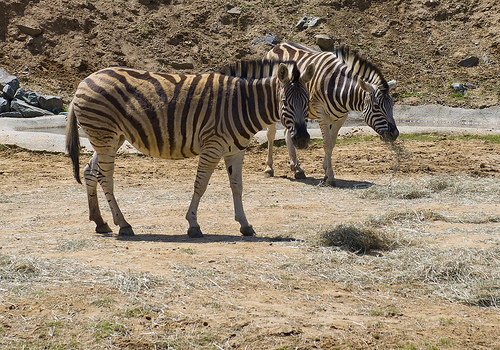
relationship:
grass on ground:
[364, 212, 463, 341] [0, 119, 500, 347]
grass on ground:
[372, 189, 480, 316] [157, 242, 212, 270]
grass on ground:
[348, 234, 425, 348] [91, 248, 236, 283]